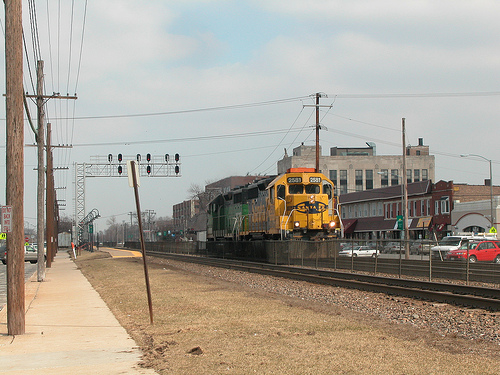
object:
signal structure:
[102, 152, 183, 177]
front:
[271, 174, 341, 257]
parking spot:
[435, 254, 493, 269]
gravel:
[351, 295, 367, 307]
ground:
[90, 242, 498, 372]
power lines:
[37, 59, 47, 283]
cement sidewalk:
[0, 248, 160, 374]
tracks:
[122, 237, 498, 307]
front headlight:
[291, 220, 300, 227]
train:
[207, 174, 342, 263]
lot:
[340, 241, 498, 262]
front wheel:
[467, 256, 477, 263]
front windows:
[287, 183, 305, 191]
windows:
[364, 168, 375, 190]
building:
[338, 177, 497, 249]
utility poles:
[24, 60, 77, 282]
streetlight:
[457, 153, 474, 161]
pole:
[488, 160, 496, 233]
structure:
[73, 153, 179, 251]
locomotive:
[248, 172, 341, 259]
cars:
[208, 179, 272, 234]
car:
[428, 236, 492, 260]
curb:
[373, 254, 499, 264]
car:
[446, 239, 498, 263]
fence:
[334, 239, 499, 283]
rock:
[293, 283, 310, 293]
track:
[316, 258, 499, 312]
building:
[277, 138, 435, 196]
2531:
[288, 178, 300, 184]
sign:
[399, 218, 408, 230]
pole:
[401, 118, 410, 261]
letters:
[0, 204, 12, 236]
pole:
[6, 0, 27, 333]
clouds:
[94, 12, 213, 65]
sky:
[91, 3, 499, 85]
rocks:
[360, 295, 372, 304]